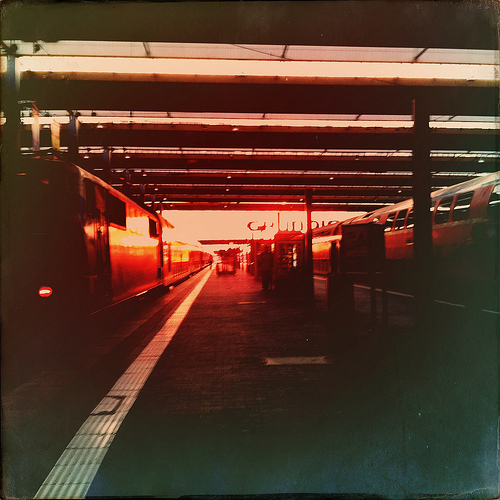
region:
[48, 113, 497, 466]
reflection in tunnel is red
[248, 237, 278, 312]
person in dark walking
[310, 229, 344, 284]
person standing next to train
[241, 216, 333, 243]
sign on the back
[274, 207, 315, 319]
booth in middle of pavement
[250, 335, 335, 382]
silver object on the floor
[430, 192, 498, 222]
windows on the train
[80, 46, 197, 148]
the roof of a train station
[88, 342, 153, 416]
the safety line of a train station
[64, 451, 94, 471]
the ridges of a safety line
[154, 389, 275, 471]
the cement part of a train station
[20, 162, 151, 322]
the front of the train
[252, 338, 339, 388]
a gray metal sewer cover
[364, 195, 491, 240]
the windows of a train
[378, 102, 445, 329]
a tall wooden pillar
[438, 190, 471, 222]
a window on the train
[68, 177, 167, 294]
a train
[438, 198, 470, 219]
the train has windows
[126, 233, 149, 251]
reflection of light on the train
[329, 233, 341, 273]
a person standing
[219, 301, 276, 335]
the ground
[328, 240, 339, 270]
person standing by the train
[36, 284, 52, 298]
a red light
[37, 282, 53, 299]
a small red light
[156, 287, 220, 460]
platform of the railway station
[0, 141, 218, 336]
train in the railway station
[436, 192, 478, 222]
window of the train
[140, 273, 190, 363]
platform marked with white color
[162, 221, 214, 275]
reflection of sun in the railway station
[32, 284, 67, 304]
indicator of the train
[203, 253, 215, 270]
person standing in the platform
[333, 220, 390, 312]
small shop in the platform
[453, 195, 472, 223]
window made with glass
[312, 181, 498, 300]
train on the track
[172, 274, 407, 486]
platform between the trains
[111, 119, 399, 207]
lights on the ceiling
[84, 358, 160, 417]
strip on the platform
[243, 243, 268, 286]
person on the platform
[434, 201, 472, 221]
windows on the train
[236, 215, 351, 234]
lettering on the wall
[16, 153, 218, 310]
The train to the left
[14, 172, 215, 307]
A train to the left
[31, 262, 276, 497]
The thick white line to the left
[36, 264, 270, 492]
A thick white line to the left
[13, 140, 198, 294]
long subway train sheltered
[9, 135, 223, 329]
long subway train sheltered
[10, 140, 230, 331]
long subway train sheltered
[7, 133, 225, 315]
long subway train sheltered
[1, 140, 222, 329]
long subway train sheltered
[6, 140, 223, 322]
long subway train sheltered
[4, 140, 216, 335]
long subway train sheltered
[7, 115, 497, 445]
train station at sunset is beautiful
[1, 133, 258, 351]
the sun reflects off the train at dusk as it leaves the station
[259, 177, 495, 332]
those arriving the train station eagerly await as they come to a halt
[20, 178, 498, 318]
nobody gets off the trains as they are coming in the station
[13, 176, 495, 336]
traffic is slow at dusk in the train station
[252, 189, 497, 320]
only few people await to enter on to the train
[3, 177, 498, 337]
dusk is the best time for traveling by train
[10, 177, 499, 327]
this stop is one of peace and calmity for the trains